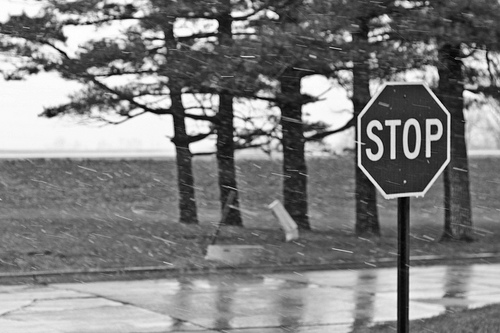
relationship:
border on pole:
[355, 82, 451, 199] [393, 195, 415, 332]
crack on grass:
[0, 264, 500, 333] [2, 155, 500, 333]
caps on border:
[365, 118, 446, 161] [355, 82, 451, 199]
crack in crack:
[118, 295, 146, 315] [0, 264, 500, 333]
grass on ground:
[2, 155, 497, 285] [1, 262, 498, 329]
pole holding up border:
[394, 195, 410, 333] [355, 82, 451, 199]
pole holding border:
[394, 193, 416, 331] [355, 82, 451, 199]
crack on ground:
[0, 264, 500, 333] [83, 268, 338, 328]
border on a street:
[355, 82, 451, 199] [0, 261, 497, 331]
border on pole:
[355, 82, 451, 199] [392, 188, 418, 330]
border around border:
[349, 78, 458, 199] [355, 82, 451, 199]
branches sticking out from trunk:
[5, 11, 164, 121] [163, 73, 349, 213]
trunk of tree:
[279, 75, 308, 230] [7, 2, 212, 226]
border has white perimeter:
[355, 82, 451, 199] [447, 114, 452, 161]